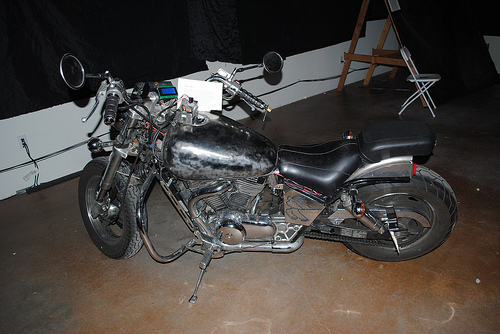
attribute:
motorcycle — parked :
[46, 40, 470, 275]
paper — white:
[175, 77, 223, 115]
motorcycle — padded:
[41, 47, 473, 332]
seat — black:
[266, 118, 371, 188]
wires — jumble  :
[120, 105, 155, 162]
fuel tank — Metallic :
[172, 144, 264, 179]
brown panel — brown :
[283, 186, 324, 226]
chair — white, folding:
[394, 45, 444, 120]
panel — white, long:
[3, 36, 388, 201]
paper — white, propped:
[181, 73, 229, 108]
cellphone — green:
[157, 85, 179, 100]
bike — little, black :
[76, 72, 431, 245]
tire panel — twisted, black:
[349, 156, 411, 180]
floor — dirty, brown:
[8, 42, 497, 332]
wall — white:
[1, 2, 84, 194]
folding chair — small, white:
[388, 40, 463, 126]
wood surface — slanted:
[383, 0, 485, 105]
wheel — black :
[78, 154, 147, 261]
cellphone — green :
[146, 76, 182, 103]